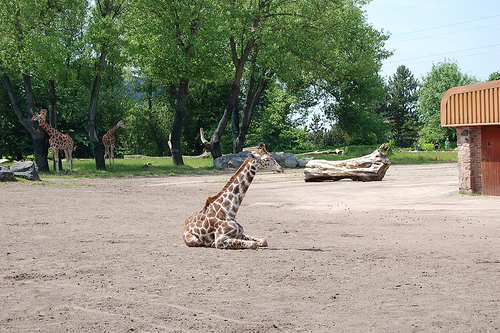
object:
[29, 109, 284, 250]
giraffes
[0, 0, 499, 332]
park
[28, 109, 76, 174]
giraffe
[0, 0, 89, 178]
tree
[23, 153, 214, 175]
grass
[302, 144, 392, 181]
tree stump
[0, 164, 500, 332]
ground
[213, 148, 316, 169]
rocks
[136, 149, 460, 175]
grass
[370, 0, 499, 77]
sky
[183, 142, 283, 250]
giraffe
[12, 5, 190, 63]
leaves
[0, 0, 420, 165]
trees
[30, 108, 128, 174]
giraffes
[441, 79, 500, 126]
roof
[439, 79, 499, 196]
building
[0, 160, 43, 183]
rocks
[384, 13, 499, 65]
powerlines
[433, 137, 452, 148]
people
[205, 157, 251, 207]
mane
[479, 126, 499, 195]
door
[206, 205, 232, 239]
pattern